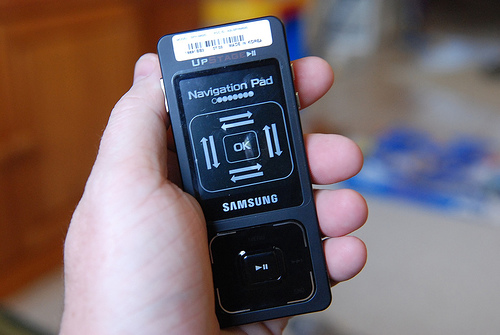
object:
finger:
[286, 38, 386, 284]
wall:
[0, 2, 195, 277]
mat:
[330, 117, 500, 216]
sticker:
[174, 19, 272, 64]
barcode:
[185, 32, 250, 54]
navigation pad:
[187, 72, 285, 105]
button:
[239, 251, 292, 280]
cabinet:
[60, 51, 207, 307]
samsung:
[217, 194, 287, 212]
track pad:
[180, 95, 294, 195]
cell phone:
[156, 12, 331, 329]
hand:
[59, 53, 369, 333]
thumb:
[109, 35, 179, 157]